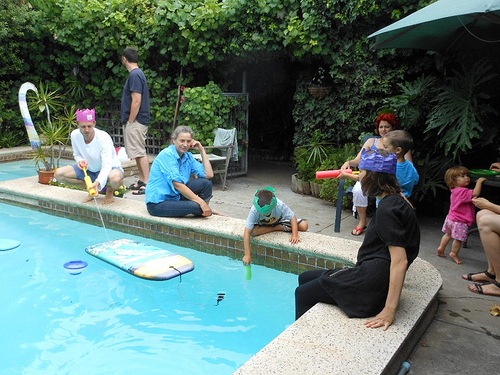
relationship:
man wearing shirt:
[162, 131, 202, 156] [145, 155, 179, 204]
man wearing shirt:
[144, 125, 225, 220] [143, 144, 205, 204]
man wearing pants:
[144, 125, 225, 220] [141, 174, 215, 221]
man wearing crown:
[293, 144, 423, 332] [359, 148, 398, 175]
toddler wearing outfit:
[435, 162, 484, 263] [433, 186, 476, 242]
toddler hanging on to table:
[435, 162, 484, 263] [463, 162, 484, 183]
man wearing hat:
[293, 144, 422, 331] [344, 147, 424, 182]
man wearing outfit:
[293, 144, 422, 331] [291, 190, 422, 320]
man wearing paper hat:
[53, 109, 125, 205] [71, 105, 97, 123]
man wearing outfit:
[53, 109, 125, 205] [68, 127, 125, 188]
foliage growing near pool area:
[47, 14, 319, 146] [1, 138, 484, 373]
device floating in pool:
[63, 257, 89, 275] [1, 144, 441, 373]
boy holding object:
[378, 123, 429, 221] [315, 169, 360, 179]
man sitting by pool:
[293, 144, 422, 331] [1, 192, 316, 373]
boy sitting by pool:
[241, 187, 308, 268] [1, 192, 316, 373]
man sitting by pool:
[144, 125, 225, 220] [1, 192, 316, 373]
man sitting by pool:
[53, 109, 125, 205] [1, 192, 316, 373]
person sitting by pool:
[339, 113, 412, 238] [1, 192, 316, 373]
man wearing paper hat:
[53, 109, 124, 207] [76, 108, 95, 122]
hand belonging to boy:
[242, 251, 252, 264] [241, 187, 308, 268]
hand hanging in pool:
[242, 251, 252, 264] [0, 145, 353, 374]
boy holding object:
[375, 130, 421, 210] [314, 166, 361, 179]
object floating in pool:
[85, 232, 195, 282] [5, 189, 424, 371]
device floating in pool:
[63, 260, 88, 276] [5, 189, 424, 371]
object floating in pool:
[0, 235, 21, 253] [5, 189, 424, 371]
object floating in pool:
[243, 255, 253, 283] [5, 189, 424, 371]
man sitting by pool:
[293, 144, 422, 331] [0, 145, 353, 374]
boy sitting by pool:
[241, 187, 308, 268] [0, 145, 353, 374]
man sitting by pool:
[144, 125, 225, 220] [0, 145, 353, 374]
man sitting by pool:
[53, 109, 125, 205] [0, 145, 353, 374]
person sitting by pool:
[339, 113, 412, 238] [0, 145, 353, 374]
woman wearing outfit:
[293, 144, 420, 331] [318, 194, 421, 319]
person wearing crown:
[340, 113, 412, 236] [357, 146, 398, 175]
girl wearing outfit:
[436, 181, 496, 245] [446, 187, 475, 225]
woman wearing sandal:
[453, 167, 498, 299] [460, 266, 497, 287]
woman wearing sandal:
[453, 167, 498, 299] [465, 276, 498, 296]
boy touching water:
[238, 182, 308, 267] [94, 221, 223, 373]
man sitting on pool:
[119, 47, 152, 195] [1, 144, 441, 373]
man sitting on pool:
[144, 125, 225, 220] [1, 144, 441, 373]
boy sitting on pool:
[241, 187, 308, 268] [1, 144, 441, 373]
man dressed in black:
[293, 144, 422, 331] [296, 194, 420, 321]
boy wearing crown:
[241, 187, 308, 268] [254, 187, 275, 212]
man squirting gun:
[53, 109, 125, 205] [81, 160, 98, 202]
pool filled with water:
[1, 144, 441, 373] [3, 155, 298, 373]